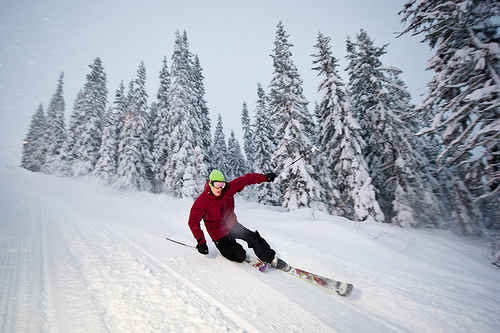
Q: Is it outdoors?
A: Yes, it is outdoors.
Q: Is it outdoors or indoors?
A: It is outdoors.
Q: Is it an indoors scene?
A: No, it is outdoors.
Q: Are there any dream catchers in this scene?
A: No, there are no dream catchers.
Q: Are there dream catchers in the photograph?
A: No, there are no dream catchers.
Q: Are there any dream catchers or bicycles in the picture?
A: No, there are no dream catchers or bicycles.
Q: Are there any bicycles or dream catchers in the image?
A: No, there are no dream catchers or bicycles.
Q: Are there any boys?
A: No, there are no boys.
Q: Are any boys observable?
A: No, there are no boys.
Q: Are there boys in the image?
A: No, there are no boys.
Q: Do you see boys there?
A: No, there are no boys.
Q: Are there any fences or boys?
A: No, there are no boys or fences.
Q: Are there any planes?
A: No, there are no planes.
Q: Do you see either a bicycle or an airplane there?
A: No, there are no airplanes or bicycles.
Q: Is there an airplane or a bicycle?
A: No, there are no airplanes or bicycles.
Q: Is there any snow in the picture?
A: Yes, there is snow.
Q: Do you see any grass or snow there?
A: Yes, there is snow.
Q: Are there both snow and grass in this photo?
A: No, there is snow but no grass.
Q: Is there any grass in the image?
A: No, there is no grass.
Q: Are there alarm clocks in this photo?
A: No, there are no alarm clocks.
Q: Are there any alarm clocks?
A: No, there are no alarm clocks.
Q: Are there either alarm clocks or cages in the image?
A: No, there are no alarm clocks or cages.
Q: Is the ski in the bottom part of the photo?
A: Yes, the ski is in the bottom of the image.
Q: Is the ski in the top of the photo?
A: No, the ski is in the bottom of the image.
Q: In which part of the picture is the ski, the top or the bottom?
A: The ski is in the bottom of the image.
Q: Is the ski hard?
A: Yes, the ski is hard.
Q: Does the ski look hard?
A: Yes, the ski is hard.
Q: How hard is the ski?
A: The ski is hard.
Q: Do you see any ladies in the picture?
A: No, there are no ladies.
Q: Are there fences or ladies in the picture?
A: No, there are no ladies or fences.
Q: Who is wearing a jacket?
A: The man is wearing a jacket.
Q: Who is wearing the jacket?
A: The man is wearing a jacket.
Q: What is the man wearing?
A: The man is wearing a jacket.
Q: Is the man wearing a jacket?
A: Yes, the man is wearing a jacket.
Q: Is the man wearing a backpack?
A: No, the man is wearing a jacket.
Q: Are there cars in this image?
A: No, there are no cars.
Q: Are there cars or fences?
A: No, there are no cars or fences.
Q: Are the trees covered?
A: Yes, the trees are covered.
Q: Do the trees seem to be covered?
A: Yes, the trees are covered.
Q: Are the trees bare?
A: No, the trees are covered.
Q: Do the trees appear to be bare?
A: No, the trees are covered.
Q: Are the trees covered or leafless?
A: The trees are covered.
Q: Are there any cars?
A: No, there are no cars.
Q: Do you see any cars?
A: No, there are no cars.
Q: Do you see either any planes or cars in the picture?
A: No, there are no cars or planes.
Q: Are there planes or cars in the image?
A: No, there are no cars or planes.